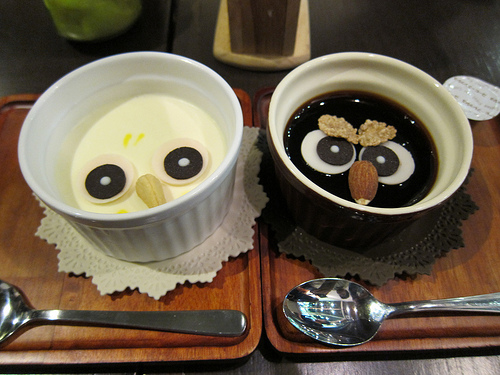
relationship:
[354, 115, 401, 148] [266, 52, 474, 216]
flake side bowl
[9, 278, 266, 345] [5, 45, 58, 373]
spoon on left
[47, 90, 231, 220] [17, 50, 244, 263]
cream on bowl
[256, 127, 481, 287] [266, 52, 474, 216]
cloth under bowl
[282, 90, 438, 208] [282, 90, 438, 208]
chocolate in chocolate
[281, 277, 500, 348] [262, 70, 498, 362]
silver on plate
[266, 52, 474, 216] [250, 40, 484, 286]
bowl on cloth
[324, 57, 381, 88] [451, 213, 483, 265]
bowl on tray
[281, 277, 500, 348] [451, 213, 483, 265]
silver on tray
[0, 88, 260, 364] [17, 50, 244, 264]
plates under bowl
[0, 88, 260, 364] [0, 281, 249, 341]
plates under spoon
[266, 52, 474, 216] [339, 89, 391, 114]
bowl has chocolate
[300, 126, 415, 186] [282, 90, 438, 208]
eyes on chocolate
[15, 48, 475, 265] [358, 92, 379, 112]
two cups of coffee